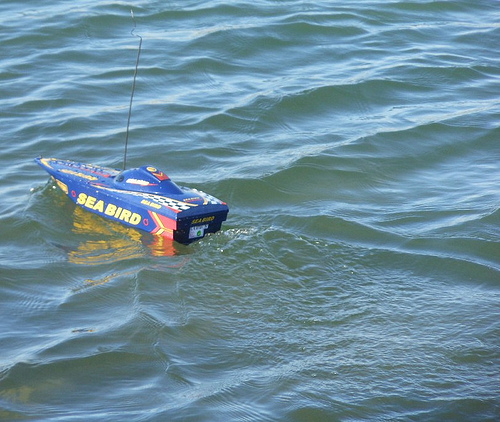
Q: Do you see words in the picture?
A: Yes, there are words.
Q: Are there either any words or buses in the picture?
A: Yes, there are words.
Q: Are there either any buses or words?
A: Yes, there are words.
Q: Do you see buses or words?
A: Yes, there are words.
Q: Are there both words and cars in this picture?
A: No, there are words but no cars.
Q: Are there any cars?
A: No, there are no cars.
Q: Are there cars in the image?
A: No, there are no cars.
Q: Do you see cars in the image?
A: No, there are no cars.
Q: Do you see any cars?
A: No, there are no cars.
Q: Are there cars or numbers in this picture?
A: No, there are no cars or numbers.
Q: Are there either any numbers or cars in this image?
A: No, there are no cars or numbers.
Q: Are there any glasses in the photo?
A: No, there are no glasses.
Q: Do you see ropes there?
A: No, there are no ropes.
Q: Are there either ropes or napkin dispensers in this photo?
A: No, there are no ropes or napkin dispensers.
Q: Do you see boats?
A: Yes, there is a boat.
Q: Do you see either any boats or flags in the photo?
A: Yes, there is a boat.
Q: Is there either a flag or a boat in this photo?
A: Yes, there is a boat.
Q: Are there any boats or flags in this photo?
A: Yes, there is a boat.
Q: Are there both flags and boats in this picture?
A: Yes, there are both a boat and a flag.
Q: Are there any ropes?
A: No, there are no ropes.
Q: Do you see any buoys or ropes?
A: No, there are no ropes or buoys.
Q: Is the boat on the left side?
A: Yes, the boat is on the left of the image.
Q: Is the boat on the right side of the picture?
A: No, the boat is on the left of the image.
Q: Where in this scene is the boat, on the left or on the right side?
A: The boat is on the left of the image.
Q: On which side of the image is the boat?
A: The boat is on the left of the image.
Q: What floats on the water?
A: The boat floats on the water.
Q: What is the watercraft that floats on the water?
A: The watercraft is a boat.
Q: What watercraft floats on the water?
A: The watercraft is a boat.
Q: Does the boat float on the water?
A: Yes, the boat floats on the water.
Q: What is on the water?
A: The boat is on the water.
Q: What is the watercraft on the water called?
A: The watercraft is a boat.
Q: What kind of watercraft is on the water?
A: The watercraft is a boat.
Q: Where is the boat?
A: The boat is on the water.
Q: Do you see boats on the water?
A: Yes, there is a boat on the water.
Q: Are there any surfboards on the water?
A: No, there is a boat on the water.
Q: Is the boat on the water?
A: Yes, the boat is on the water.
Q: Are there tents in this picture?
A: No, there are no tents.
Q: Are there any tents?
A: No, there are no tents.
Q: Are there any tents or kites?
A: No, there are no tents or kites.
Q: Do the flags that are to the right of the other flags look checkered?
A: Yes, the flags are checkered.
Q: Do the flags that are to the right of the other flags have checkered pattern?
A: Yes, the flags are checkered.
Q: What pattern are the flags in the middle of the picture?
A: The flags are checkered.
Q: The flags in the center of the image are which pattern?
A: The flags are checkered.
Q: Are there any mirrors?
A: No, there are no mirrors.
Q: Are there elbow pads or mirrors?
A: No, there are no mirrors or elbow pads.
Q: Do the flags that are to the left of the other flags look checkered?
A: Yes, the flags are checkered.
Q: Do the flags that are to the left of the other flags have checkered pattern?
A: Yes, the flags are checkered.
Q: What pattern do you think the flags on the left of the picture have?
A: The flags have checkered pattern.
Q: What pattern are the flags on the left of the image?
A: The flags are checkered.